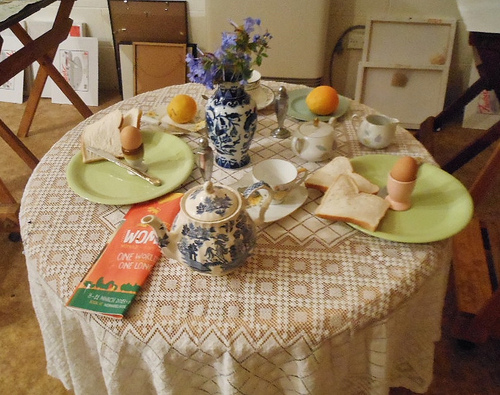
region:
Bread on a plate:
[305, 152, 395, 234]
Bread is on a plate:
[304, 153, 391, 231]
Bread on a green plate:
[306, 150, 392, 235]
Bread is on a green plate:
[305, 152, 390, 231]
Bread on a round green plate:
[300, 150, 395, 233]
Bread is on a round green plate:
[301, 152, 395, 236]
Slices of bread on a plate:
[303, 149, 393, 231]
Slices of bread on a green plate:
[301, 148, 393, 235]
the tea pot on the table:
[133, 190, 286, 273]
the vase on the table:
[189, 88, 270, 168]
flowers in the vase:
[182, 31, 257, 78]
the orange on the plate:
[302, 83, 336, 113]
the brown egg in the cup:
[379, 138, 431, 217]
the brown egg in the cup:
[112, 118, 159, 177]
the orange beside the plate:
[155, 90, 200, 137]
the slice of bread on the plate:
[318, 168, 391, 240]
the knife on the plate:
[88, 142, 158, 192]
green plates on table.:
[65, 108, 470, 250]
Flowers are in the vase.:
[180, 13, 272, 167]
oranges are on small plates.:
[165, 85, 362, 134]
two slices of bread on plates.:
[66, 108, 473, 255]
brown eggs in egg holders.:
[123, 125, 422, 212]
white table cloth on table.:
[18, 69, 455, 391]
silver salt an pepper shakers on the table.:
[179, 81, 302, 180]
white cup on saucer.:
[241, 156, 306, 224]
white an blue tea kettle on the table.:
[135, 174, 277, 278]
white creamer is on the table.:
[347, 114, 408, 147]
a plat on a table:
[71, 122, 176, 220]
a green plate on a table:
[66, 79, 238, 225]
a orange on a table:
[147, 84, 224, 145]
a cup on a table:
[243, 154, 308, 225]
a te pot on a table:
[141, 152, 287, 282]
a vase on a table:
[168, 75, 277, 186]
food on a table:
[31, 13, 376, 335]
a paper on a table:
[81, 180, 204, 340]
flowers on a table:
[157, 18, 306, 103]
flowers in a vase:
[151, 11, 322, 173]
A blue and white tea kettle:
[139, 177, 276, 278]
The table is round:
[15, 71, 452, 391]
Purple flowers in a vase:
[180, 12, 276, 172]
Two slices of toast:
[302, 154, 391, 234]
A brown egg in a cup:
[383, 152, 424, 213]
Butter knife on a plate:
[88, 144, 165, 193]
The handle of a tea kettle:
[240, 177, 278, 238]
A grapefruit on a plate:
[281, 82, 355, 130]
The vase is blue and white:
[202, 70, 263, 171]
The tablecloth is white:
[16, 79, 455, 394]